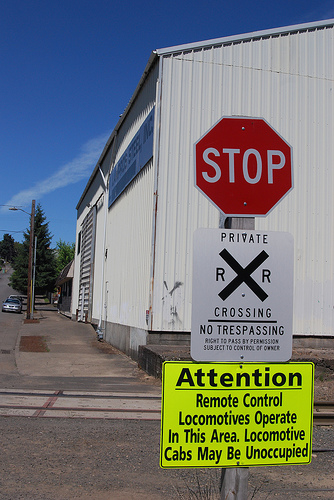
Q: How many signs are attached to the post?
A: 3.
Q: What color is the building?
A: White.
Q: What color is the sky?
A: Clear blue.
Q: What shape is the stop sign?
A: Octagon.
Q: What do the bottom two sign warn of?
A: Railroad crossing.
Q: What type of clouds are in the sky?
A: White wispy clouds.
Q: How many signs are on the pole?
A: 3.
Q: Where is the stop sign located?
A: On top of pole.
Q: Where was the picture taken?
A: On a street.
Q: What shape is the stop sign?
A: Octagon.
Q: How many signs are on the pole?
A: 3.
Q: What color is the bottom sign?
A: Yellow.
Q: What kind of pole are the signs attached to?
A: Wooden.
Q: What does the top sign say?
A: STOP.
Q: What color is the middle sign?
A: White.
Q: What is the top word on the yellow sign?
A: Attention.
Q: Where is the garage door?
A: On the building.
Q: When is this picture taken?
A: In the daytime.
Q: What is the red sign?
A: A stop sign.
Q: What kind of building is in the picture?
A: A metal building.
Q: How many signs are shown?
A: Three.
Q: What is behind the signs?
A: A railroad track.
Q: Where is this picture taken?
A: At a railroad track.